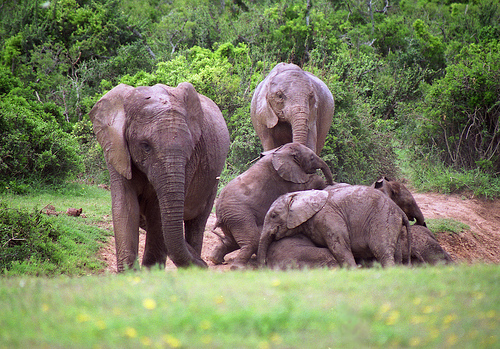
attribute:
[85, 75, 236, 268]
elephant — large, gray, standing, adult, grey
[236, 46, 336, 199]
elephant — female, grey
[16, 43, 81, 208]
vegetation — green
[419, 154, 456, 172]
ground — young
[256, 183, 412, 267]
elephant — large, gray, small, playing, young, grey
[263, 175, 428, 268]
elephant — large, gray, playing, grey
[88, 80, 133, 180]
ear — large, ruffled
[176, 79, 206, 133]
ear — large, ruffled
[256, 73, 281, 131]
ear — large, ruffled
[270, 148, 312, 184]
ear — large, ruffled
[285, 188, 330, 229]
ear — large, ruffled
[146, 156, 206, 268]
trunk — large, ridged, wrinkled, long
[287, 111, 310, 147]
trunk — large, ridged, wrinkled, long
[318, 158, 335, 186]
trunk — large, ridged, wrinkled, long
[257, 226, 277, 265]
trunk — large, ridged, wrinkled, long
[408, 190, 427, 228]
trunk — large, ridged, wrinkled, long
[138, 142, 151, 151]
eye — small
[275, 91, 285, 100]
eye — small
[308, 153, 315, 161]
eye — small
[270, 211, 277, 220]
eye — small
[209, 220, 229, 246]
tail — long, thin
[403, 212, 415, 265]
tail — long, thin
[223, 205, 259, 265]
leg — bent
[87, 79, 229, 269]
elephants — adult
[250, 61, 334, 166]
elephants — adult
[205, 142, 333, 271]
elephants — young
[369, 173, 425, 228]
elephants — young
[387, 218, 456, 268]
elephants — young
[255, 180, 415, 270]
elephants — young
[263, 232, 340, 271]
elephants — young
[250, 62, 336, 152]
elephant — large, gray, standing, adult, grey, old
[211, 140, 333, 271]
elephant — large, gray, small, playing, young, climbing, grey, baby